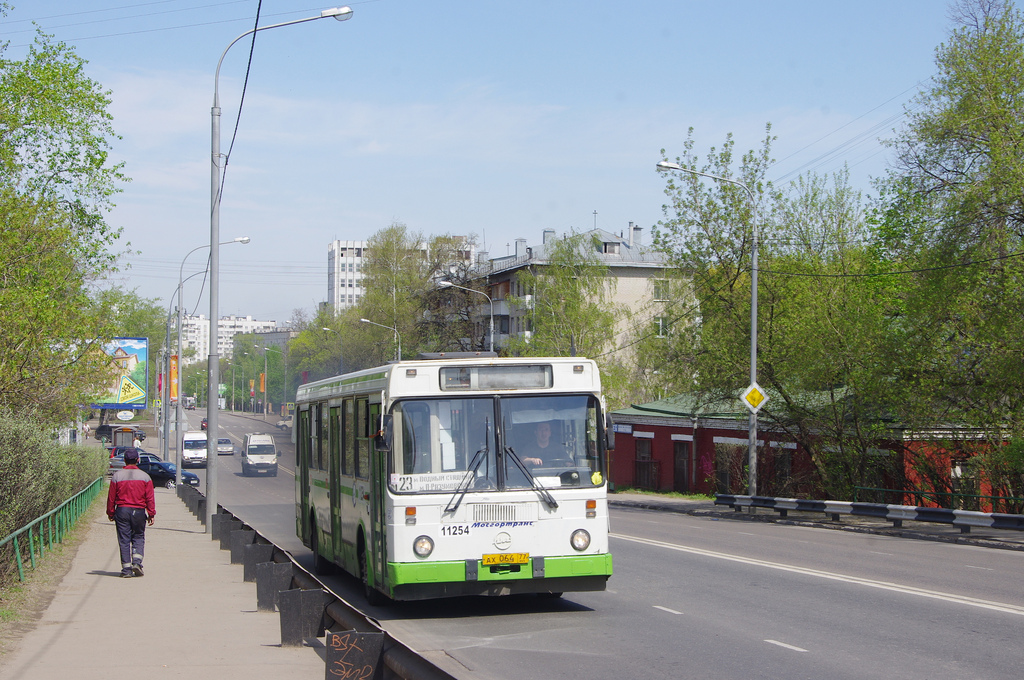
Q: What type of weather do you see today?
A: It is clear.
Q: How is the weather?
A: It is clear.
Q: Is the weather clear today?
A: Yes, it is clear.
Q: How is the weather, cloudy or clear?
A: It is clear.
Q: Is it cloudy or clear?
A: It is clear.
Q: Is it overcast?
A: No, it is clear.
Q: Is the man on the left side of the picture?
A: Yes, the man is on the left of the image.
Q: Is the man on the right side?
A: No, the man is on the left of the image.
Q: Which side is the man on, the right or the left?
A: The man is on the left of the image.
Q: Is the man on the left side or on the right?
A: The man is on the left of the image.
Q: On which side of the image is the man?
A: The man is on the left of the image.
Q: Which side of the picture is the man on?
A: The man is on the left of the image.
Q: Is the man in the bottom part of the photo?
A: Yes, the man is in the bottom of the image.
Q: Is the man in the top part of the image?
A: No, the man is in the bottom of the image.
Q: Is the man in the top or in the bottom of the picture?
A: The man is in the bottom of the image.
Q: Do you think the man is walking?
A: Yes, the man is walking.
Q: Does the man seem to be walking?
A: Yes, the man is walking.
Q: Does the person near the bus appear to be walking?
A: Yes, the man is walking.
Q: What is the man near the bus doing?
A: The man is walking.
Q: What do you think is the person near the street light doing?
A: The man is walking.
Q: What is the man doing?
A: The man is walking.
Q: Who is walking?
A: The man is walking.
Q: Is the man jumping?
A: No, the man is walking.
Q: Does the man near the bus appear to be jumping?
A: No, the man is walking.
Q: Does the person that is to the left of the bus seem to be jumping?
A: No, the man is walking.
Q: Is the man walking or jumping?
A: The man is walking.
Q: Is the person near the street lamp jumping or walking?
A: The man is walking.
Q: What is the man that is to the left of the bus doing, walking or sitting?
A: The man is walking.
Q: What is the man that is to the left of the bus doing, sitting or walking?
A: The man is walking.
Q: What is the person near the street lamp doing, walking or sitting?
A: The man is walking.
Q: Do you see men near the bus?
A: Yes, there is a man near the bus.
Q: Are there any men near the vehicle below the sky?
A: Yes, there is a man near the bus.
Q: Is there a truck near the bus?
A: No, there is a man near the bus.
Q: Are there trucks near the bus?
A: No, there is a man near the bus.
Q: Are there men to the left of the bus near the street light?
A: Yes, there is a man to the left of the bus.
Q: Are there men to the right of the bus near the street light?
A: No, the man is to the left of the bus.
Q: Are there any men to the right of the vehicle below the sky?
A: No, the man is to the left of the bus.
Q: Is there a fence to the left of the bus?
A: No, there is a man to the left of the bus.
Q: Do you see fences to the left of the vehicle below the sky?
A: No, there is a man to the left of the bus.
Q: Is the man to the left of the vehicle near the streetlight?
A: Yes, the man is to the left of the bus.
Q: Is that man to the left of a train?
A: No, the man is to the left of the bus.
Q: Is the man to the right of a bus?
A: No, the man is to the left of a bus.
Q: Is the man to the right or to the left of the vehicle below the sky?
A: The man is to the left of the bus.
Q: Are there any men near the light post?
A: Yes, there is a man near the light post.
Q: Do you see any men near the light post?
A: Yes, there is a man near the light post.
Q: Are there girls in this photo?
A: No, there are no girls.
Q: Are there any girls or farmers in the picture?
A: No, there are no girls or farmers.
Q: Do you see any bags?
A: No, there are no bags.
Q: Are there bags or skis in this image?
A: No, there are no bags or skis.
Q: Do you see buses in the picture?
A: Yes, there is a bus.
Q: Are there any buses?
A: Yes, there is a bus.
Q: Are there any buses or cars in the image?
A: Yes, there is a bus.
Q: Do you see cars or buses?
A: Yes, there is a bus.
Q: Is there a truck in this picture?
A: No, there are no trucks.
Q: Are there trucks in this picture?
A: No, there are no trucks.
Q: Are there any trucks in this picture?
A: No, there are no trucks.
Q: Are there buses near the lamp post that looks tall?
A: Yes, there is a bus near the lamp post.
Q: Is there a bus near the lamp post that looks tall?
A: Yes, there is a bus near the lamp post.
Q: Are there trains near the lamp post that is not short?
A: No, there is a bus near the street lamp.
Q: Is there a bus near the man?
A: Yes, there is a bus near the man.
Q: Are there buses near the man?
A: Yes, there is a bus near the man.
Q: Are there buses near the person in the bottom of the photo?
A: Yes, there is a bus near the man.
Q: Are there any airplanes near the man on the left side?
A: No, there is a bus near the man.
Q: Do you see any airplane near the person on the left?
A: No, there is a bus near the man.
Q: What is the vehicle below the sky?
A: The vehicle is a bus.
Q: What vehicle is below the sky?
A: The vehicle is a bus.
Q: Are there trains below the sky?
A: No, there is a bus below the sky.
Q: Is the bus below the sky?
A: Yes, the bus is below the sky.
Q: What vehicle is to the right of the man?
A: The vehicle is a bus.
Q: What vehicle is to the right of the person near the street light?
A: The vehicle is a bus.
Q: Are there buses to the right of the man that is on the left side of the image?
A: Yes, there is a bus to the right of the man.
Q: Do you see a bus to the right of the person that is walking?
A: Yes, there is a bus to the right of the man.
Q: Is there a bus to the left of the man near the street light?
A: No, the bus is to the right of the man.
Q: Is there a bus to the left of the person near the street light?
A: No, the bus is to the right of the man.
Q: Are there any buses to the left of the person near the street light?
A: No, the bus is to the right of the man.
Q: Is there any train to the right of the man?
A: No, there is a bus to the right of the man.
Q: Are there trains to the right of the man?
A: No, there is a bus to the right of the man.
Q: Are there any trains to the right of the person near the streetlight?
A: No, there is a bus to the right of the man.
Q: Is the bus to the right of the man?
A: Yes, the bus is to the right of the man.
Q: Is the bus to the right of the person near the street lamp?
A: Yes, the bus is to the right of the man.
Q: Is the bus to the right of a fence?
A: No, the bus is to the right of the man.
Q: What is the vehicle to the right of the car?
A: The vehicle is a bus.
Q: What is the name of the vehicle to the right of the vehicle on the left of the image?
A: The vehicle is a bus.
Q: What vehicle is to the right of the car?
A: The vehicle is a bus.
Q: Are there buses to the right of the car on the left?
A: Yes, there is a bus to the right of the car.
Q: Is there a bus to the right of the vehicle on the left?
A: Yes, there is a bus to the right of the car.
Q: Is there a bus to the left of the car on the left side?
A: No, the bus is to the right of the car.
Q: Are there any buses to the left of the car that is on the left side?
A: No, the bus is to the right of the car.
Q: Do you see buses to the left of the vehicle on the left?
A: No, the bus is to the right of the car.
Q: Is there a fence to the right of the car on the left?
A: No, there is a bus to the right of the car.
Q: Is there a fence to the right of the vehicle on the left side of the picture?
A: No, there is a bus to the right of the car.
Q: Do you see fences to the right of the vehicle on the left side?
A: No, there is a bus to the right of the car.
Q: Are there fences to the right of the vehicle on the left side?
A: No, there is a bus to the right of the car.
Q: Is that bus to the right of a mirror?
A: No, the bus is to the right of a car.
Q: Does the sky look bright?
A: Yes, the sky is bright.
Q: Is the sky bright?
A: Yes, the sky is bright.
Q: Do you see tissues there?
A: No, there are no tissues.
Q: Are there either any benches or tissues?
A: No, there are no tissues or benches.